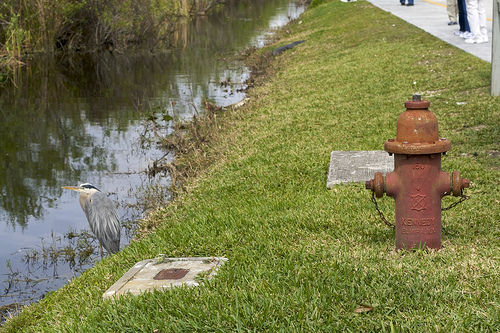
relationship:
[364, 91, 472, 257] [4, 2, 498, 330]
fire hydrant sitting in grass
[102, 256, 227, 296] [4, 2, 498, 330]
concrete block laying in grass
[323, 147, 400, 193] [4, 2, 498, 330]
concrete block laying in grass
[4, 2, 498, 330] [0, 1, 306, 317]
grass beside of water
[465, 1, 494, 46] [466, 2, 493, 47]
person wearing pants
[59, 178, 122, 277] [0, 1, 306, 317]
bird beside of water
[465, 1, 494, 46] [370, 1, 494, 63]
person standing on sidewalk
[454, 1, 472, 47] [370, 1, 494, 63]
person standing on sidewalk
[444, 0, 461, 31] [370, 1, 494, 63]
person standing on sidewalk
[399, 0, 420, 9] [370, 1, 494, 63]
person standing on sidewalk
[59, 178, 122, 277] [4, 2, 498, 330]
bird standing on grass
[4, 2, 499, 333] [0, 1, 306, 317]
grass growing in water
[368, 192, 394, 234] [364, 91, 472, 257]
chain hanging on fire hydrant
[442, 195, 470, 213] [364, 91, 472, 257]
chain hanging on fire hydrant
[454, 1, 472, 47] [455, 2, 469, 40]
person wearing pants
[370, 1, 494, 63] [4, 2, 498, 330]
sidewalk beside of grass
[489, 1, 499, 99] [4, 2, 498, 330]
post in grass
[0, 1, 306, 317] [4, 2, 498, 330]
water beside of grass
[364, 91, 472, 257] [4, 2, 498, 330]
fire hydrant standing in grass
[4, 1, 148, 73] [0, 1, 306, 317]
plants beside of water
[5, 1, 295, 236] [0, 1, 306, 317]
reflections in water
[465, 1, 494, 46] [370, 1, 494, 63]
person on sidewalk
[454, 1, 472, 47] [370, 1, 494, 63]
person on sidewalk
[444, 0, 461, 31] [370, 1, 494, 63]
person on sidewalk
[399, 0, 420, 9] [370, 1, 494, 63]
person on sidewalk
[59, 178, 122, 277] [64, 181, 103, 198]
bird has a head